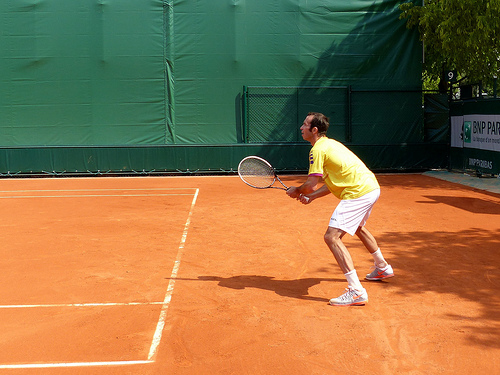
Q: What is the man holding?
A: Racket.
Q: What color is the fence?
A: Green.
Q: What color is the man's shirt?
A: Yellow.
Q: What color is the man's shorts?
A: White.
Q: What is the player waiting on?
A: The ball.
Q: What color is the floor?
A: Orange.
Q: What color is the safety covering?
A: Green.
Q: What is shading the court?
A: Trees.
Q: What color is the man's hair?
A: Brown.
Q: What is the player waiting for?
A: The serve.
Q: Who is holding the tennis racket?
A: Tennis player.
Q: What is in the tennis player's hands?
A: Tennis racket.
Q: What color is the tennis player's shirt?
A: Yellow.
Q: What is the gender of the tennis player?
A: Male.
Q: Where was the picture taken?
A: Tennis court.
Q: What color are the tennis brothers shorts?
A: White.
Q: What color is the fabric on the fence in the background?
A: Green.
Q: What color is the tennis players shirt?
A: Yellow.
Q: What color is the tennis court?
A: Orange.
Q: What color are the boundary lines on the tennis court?
A: White.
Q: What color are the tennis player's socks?
A: White.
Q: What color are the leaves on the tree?
A: Green.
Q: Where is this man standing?
A: Tennis court.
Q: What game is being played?
A: Tennis.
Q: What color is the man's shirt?
A: Yellow.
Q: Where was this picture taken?
A: A tennis court.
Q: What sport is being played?
A: Tennis.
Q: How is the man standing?
A: Feet shoulder width apart.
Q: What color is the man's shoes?
A: White.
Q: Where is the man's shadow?
A: On the ground.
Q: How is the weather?
A: Sunny.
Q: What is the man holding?
A: Tennis racket.